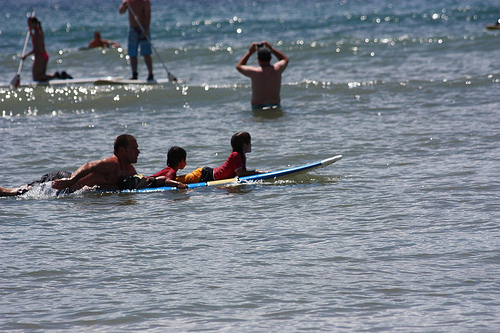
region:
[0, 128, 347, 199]
Man and children on surfboard.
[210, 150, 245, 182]
Child dressed in red shirt.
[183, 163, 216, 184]
Child dressed in orange and black shorts.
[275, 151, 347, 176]
Tip of blue and white surfboard.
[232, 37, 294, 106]
Man standing in water taking picture.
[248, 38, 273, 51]
Man holding camera in hands.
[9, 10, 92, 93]
Woman kneeling on paddle board.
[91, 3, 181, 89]
Man standing on paddle board.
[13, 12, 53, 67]
Woman dressed in pink bikini.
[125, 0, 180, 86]
Paddle in man's hands.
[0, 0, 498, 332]
A group of people in the sea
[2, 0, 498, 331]
The blue cold water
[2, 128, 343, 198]
A surfing trainer training kids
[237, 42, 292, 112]
The shirtless man with a camera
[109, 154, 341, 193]
The blue and white surf board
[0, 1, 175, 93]
The people rowing in the water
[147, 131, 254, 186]
The two kids laying down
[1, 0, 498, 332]
An open day in the sea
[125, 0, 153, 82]
The man wearing blue shorts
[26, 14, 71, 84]
The woman wearing pink swimming underpants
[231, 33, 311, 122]
Man without shirt in water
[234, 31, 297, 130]
Man standing in water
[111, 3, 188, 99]
Man standing on paddle board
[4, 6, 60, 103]
Person holding a paddle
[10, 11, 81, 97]
Person kneeling on a paddle board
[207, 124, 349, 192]
Boy on a surfboard in water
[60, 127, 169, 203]
Man lying on board in water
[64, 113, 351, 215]
Man and two children in water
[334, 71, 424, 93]
small white cap wave in ocean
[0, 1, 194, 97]
Two people on paddle boards in water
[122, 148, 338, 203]
blue and white surfboard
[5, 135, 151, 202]
man in the water on a surfboard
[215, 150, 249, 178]
child's red shirt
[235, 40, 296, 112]
man with a camera in the water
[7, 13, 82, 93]
a woman on her knees on a paddleboard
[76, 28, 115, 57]
a man in the deep water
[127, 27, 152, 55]
blue swim trunks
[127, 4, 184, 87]
man holding a paddle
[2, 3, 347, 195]
people swimming in the water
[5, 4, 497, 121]
light reflecting on the water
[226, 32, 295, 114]
a man taking a photo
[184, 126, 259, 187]
a child on a surfboard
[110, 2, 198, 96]
a man wearing blue shorts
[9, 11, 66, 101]
a woman wearing a red bikini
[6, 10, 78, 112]
a woman paddling in the water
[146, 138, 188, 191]
a little boy on a surdboard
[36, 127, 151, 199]
a man pushing children in the water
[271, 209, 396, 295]
ripples on the surface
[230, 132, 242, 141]
wet brown hair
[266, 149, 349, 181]
a the tip of a blue and white surfboard